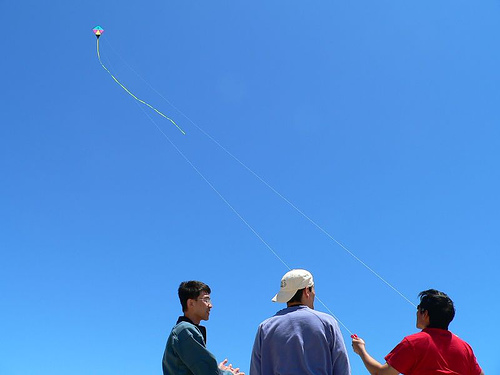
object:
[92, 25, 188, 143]
kite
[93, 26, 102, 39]
diamond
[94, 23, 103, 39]
colors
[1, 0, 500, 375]
sky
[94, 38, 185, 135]
yellow string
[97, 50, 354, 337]
main strings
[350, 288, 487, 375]
man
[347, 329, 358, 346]
handle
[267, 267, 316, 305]
hat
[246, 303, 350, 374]
blue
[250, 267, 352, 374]
man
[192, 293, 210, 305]
glasses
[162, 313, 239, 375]
jacket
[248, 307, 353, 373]
shirt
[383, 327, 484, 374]
shirt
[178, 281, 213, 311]
hair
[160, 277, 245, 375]
men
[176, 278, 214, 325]
head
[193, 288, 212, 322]
face